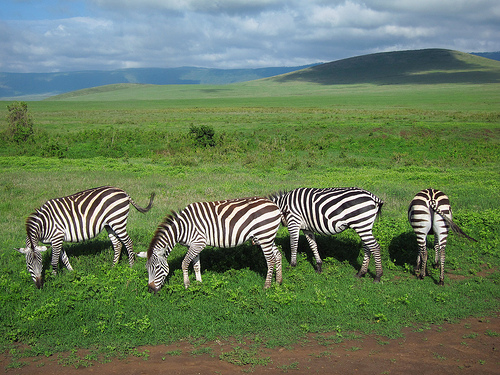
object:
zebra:
[13, 185, 156, 290]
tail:
[121, 189, 156, 215]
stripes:
[13, 185, 156, 290]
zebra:
[136, 196, 287, 295]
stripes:
[198, 199, 255, 250]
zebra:
[260, 186, 386, 285]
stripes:
[287, 191, 371, 224]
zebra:
[408, 187, 478, 286]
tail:
[429, 200, 478, 243]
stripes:
[435, 198, 450, 210]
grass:
[0, 48, 499, 374]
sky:
[0, 0, 499, 103]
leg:
[303, 230, 323, 274]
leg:
[285, 214, 302, 270]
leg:
[349, 215, 384, 283]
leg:
[409, 209, 431, 279]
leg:
[432, 227, 448, 287]